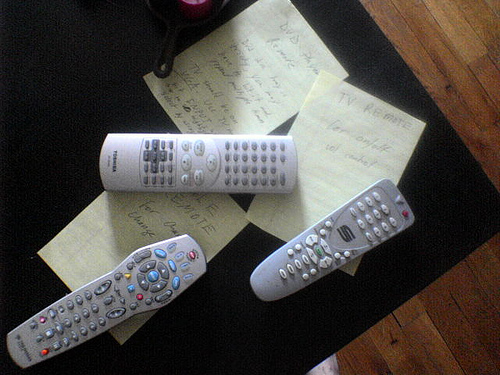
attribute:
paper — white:
[239, 61, 431, 283]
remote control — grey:
[97, 132, 296, 194]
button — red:
[401, 206, 408, 220]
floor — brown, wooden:
[295, 1, 496, 373]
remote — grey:
[268, 181, 413, 301]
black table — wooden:
[124, 297, 306, 373]